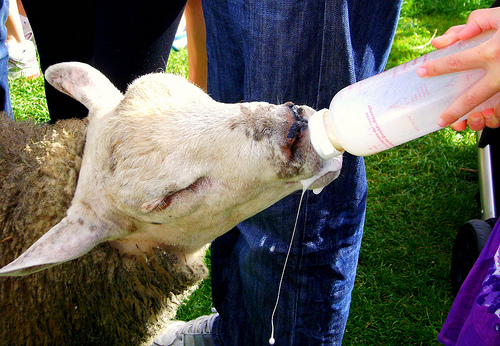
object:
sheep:
[0, 61, 342, 346]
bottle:
[305, 26, 499, 160]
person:
[417, 5, 500, 137]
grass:
[402, 0, 463, 25]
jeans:
[197, 0, 403, 346]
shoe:
[153, 310, 221, 345]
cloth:
[437, 216, 499, 345]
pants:
[18, 0, 192, 126]